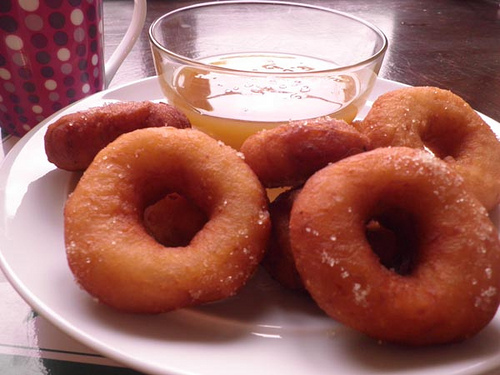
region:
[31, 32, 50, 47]
polka dot on coffee cup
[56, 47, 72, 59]
polka dot on coffee cup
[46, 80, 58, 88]
polka dot on coffee cup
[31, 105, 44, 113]
polka dot on coffee cup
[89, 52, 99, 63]
polka dot on coffee cup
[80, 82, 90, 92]
polka dot on coffee cup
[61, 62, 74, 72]
polka dot on coffee cup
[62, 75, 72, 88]
polka dot on coffee cup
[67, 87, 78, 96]
polka dot on coffee cup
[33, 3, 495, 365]
plate of round donuts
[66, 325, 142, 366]
edge of white plate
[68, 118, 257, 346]
light brown donut on plate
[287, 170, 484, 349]
light brown donut on plate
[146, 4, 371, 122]
bowl of syrup on plate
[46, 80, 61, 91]
polka dot on cup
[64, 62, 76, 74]
polka dot on cup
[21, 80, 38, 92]
polka dot on cup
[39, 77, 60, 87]
polka dot on cup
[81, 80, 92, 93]
polka dot on cup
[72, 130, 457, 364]
donuts on a plate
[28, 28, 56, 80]
three purple poke a dots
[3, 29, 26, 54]
a white dot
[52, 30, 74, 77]
a purple. white, and pink dot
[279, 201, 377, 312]
a sugar coated donut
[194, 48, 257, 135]
sauce in a glass bowl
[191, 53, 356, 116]
a glass bowl half full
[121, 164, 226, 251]
a hole of a donut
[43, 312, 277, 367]
a white plate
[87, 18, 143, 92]
the handle of a mug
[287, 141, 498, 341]
a golden brown onion ring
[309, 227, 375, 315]
salt sprinkled on an onion ring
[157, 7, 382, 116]
a dipping sauce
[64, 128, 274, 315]
an onion ring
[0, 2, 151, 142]
a pink polka dotted coffee mug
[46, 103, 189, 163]
a deep brown onion ring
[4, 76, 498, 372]
a round white dinner plate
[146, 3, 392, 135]
a small glass container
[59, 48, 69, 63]
a white polka dot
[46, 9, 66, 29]
a mauve polka dot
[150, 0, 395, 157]
a small glass container of a sauce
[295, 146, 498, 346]
an onion ring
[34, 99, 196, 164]
an onion ring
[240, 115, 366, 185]
an onion ring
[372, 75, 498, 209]
an onion ring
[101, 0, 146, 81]
a white handle on a mug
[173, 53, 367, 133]
sauce in a small glass